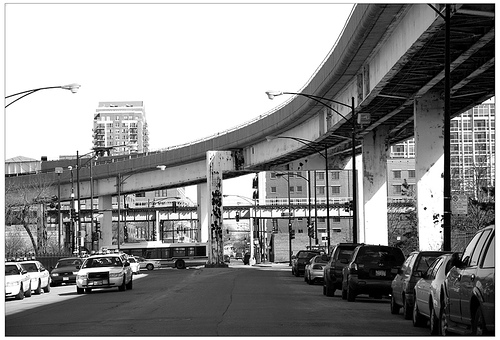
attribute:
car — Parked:
[281, 244, 316, 276]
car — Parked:
[305, 251, 328, 284]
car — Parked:
[325, 242, 362, 296]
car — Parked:
[343, 240, 406, 301]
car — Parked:
[388, 247, 443, 317]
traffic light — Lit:
[233, 208, 245, 220]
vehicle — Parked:
[341, 243, 404, 299]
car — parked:
[51, 246, 88, 304]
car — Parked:
[286, 242, 324, 279]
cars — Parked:
[309, 210, 484, 293]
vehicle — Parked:
[317, 235, 357, 292]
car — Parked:
[339, 244, 405, 302]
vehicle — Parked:
[409, 253, 464, 333]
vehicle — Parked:
[291, 247, 321, 274]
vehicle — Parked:
[3, 262, 30, 297]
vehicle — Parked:
[18, 262, 50, 293]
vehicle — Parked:
[51, 252, 85, 284]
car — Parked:
[301, 251, 331, 282]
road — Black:
[29, 194, 397, 339]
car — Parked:
[46, 258, 78, 285]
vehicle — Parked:
[18, 259, 51, 297]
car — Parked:
[290, 247, 319, 279]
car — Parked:
[409, 249, 466, 331]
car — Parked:
[388, 246, 454, 317]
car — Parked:
[322, 236, 367, 295]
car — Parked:
[434, 223, 496, 337]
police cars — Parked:
[2, 262, 32, 297]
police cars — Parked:
[17, 260, 52, 293]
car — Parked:
[304, 246, 334, 288]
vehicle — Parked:
[389, 251, 464, 309]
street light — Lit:
[18, 67, 93, 113]